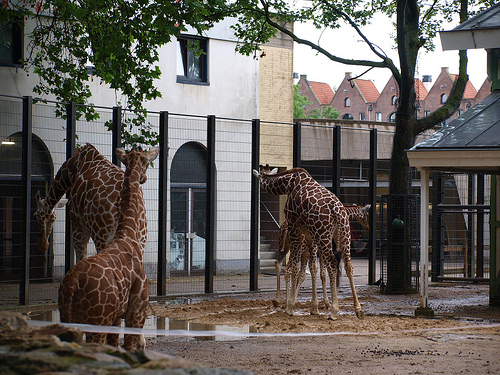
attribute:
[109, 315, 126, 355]
leg — is in the picture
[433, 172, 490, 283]
enclosure — is in the picture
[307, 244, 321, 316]
leg — is in the picture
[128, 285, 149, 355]
leg — is in the picture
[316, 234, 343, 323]
leg — is in the picture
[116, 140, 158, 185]
head — is in the picture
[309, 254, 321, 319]
leg — is in the picture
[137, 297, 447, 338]
muddy area — large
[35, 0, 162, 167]
branches — tree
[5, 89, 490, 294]
fence — black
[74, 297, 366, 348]
puddle — is in the picture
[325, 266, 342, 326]
leg — is in the picture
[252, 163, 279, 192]
head — is in the picture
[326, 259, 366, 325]
leg — is in the picture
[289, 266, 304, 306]
leg — is in the picture